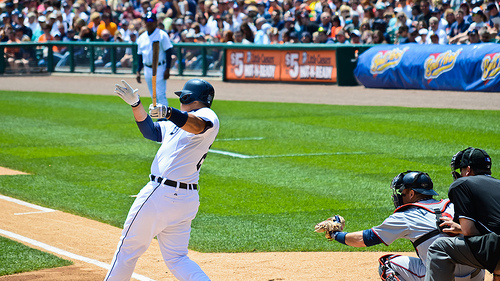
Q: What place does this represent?
A: It represents the field.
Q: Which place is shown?
A: It is a field.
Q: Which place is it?
A: It is a field.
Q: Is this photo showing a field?
A: Yes, it is showing a field.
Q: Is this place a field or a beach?
A: It is a field.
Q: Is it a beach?
A: No, it is a field.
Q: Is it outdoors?
A: Yes, it is outdoors.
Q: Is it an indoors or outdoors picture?
A: It is outdoors.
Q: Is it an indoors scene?
A: No, it is outdoors.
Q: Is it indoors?
A: No, it is outdoors.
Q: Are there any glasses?
A: No, there are no glasses.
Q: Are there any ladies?
A: No, there are no ladies.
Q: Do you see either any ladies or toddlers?
A: No, there are no ladies or toddlers.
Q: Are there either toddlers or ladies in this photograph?
A: No, there are no ladies or toddlers.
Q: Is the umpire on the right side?
A: Yes, the umpire is on the right of the image.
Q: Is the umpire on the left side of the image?
A: No, the umpire is on the right of the image.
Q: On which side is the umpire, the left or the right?
A: The umpire is on the right of the image.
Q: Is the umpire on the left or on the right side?
A: The umpire is on the right of the image.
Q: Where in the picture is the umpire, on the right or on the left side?
A: The umpire is on the right of the image.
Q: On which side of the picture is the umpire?
A: The umpire is on the right of the image.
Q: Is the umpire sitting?
A: Yes, the umpire is sitting.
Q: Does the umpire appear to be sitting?
A: Yes, the umpire is sitting.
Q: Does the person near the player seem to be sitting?
A: Yes, the umpire is sitting.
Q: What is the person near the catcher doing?
A: The umpire is sitting.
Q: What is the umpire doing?
A: The umpire is sitting.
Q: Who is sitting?
A: The umpire is sitting.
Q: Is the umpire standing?
A: No, the umpire is sitting.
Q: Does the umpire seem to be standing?
A: No, the umpire is sitting.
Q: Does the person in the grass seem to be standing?
A: No, the umpire is sitting.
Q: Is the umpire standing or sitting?
A: The umpire is sitting.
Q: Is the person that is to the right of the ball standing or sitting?
A: The umpire is sitting.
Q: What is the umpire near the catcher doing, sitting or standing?
A: The umpire is sitting.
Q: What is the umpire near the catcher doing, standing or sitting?
A: The umpire is sitting.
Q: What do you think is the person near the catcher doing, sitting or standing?
A: The umpire is sitting.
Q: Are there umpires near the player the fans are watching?
A: Yes, there is an umpire near the player.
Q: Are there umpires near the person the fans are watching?
A: Yes, there is an umpire near the player.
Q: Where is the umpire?
A: The umpire is on the field.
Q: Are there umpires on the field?
A: Yes, there is an umpire on the field.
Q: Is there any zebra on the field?
A: No, there is an umpire on the field.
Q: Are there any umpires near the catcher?
A: Yes, there is an umpire near the catcher.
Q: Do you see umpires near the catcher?
A: Yes, there is an umpire near the catcher.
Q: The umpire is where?
A: The umpire is in the grass.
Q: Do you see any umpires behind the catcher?
A: Yes, there is an umpire behind the catcher.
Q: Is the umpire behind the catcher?
A: Yes, the umpire is behind the catcher.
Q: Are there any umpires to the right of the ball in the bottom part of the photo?
A: Yes, there is an umpire to the right of the ball.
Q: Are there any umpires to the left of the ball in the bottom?
A: No, the umpire is to the right of the ball.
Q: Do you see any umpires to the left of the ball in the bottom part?
A: No, the umpire is to the right of the ball.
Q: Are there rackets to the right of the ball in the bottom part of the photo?
A: No, there is an umpire to the right of the ball.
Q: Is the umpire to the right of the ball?
A: Yes, the umpire is to the right of the ball.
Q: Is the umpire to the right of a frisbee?
A: No, the umpire is to the right of the ball.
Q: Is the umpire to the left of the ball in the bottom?
A: No, the umpire is to the right of the ball.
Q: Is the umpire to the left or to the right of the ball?
A: The umpire is to the right of the ball.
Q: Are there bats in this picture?
A: Yes, there is a bat.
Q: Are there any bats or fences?
A: Yes, there is a bat.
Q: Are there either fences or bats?
A: Yes, there is a bat.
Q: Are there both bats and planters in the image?
A: No, there is a bat but no planters.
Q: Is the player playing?
A: Yes, the player is playing.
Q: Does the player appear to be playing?
A: Yes, the player is playing.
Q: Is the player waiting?
A: No, the player is playing.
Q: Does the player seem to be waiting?
A: No, the player is playing.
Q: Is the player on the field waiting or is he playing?
A: The player is playing.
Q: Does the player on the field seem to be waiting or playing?
A: The player is playing.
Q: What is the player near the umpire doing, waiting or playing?
A: The player is playing.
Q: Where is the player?
A: The player is on the field.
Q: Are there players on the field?
A: Yes, there is a player on the field.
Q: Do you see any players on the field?
A: Yes, there is a player on the field.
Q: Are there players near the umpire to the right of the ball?
A: Yes, there is a player near the umpire.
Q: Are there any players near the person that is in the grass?
A: Yes, there is a player near the umpire.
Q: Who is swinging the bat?
A: The player is swinging the bat.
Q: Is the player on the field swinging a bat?
A: Yes, the player is swinging a bat.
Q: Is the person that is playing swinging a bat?
A: Yes, the player is swinging a bat.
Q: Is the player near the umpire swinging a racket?
A: No, the player is swinging a bat.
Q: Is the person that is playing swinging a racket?
A: No, the player is swinging a bat.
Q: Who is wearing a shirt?
A: The player is wearing a shirt.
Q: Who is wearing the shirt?
A: The player is wearing a shirt.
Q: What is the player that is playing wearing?
A: The player is wearing a shirt.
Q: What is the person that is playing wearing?
A: The player is wearing a shirt.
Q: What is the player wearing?
A: The player is wearing a shirt.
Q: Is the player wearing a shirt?
A: Yes, the player is wearing a shirt.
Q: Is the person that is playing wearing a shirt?
A: Yes, the player is wearing a shirt.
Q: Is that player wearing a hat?
A: No, the player is wearing a shirt.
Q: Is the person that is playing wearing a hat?
A: No, the player is wearing a shirt.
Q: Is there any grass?
A: Yes, there is grass.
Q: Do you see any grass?
A: Yes, there is grass.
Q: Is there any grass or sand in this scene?
A: Yes, there is grass.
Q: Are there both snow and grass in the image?
A: No, there is grass but no snow.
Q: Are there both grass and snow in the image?
A: No, there is grass but no snow.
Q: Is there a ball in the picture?
A: Yes, there is a ball.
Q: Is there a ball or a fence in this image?
A: Yes, there is a ball.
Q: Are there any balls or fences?
A: Yes, there is a ball.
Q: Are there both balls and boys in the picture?
A: No, there is a ball but no boys.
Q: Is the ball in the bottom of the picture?
A: Yes, the ball is in the bottom of the image.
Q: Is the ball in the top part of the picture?
A: No, the ball is in the bottom of the image.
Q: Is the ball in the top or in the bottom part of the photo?
A: The ball is in the bottom of the image.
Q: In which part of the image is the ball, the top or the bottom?
A: The ball is in the bottom of the image.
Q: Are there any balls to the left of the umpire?
A: Yes, there is a ball to the left of the umpire.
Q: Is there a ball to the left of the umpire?
A: Yes, there is a ball to the left of the umpire.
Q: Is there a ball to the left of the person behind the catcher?
A: Yes, there is a ball to the left of the umpire.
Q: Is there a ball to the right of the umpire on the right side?
A: No, the ball is to the left of the umpire.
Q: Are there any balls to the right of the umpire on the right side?
A: No, the ball is to the left of the umpire.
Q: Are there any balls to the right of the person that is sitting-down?
A: No, the ball is to the left of the umpire.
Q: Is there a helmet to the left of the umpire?
A: No, there is a ball to the left of the umpire.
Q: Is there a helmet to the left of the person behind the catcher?
A: No, there is a ball to the left of the umpire.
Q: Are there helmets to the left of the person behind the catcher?
A: No, there is a ball to the left of the umpire.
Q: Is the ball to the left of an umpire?
A: Yes, the ball is to the left of an umpire.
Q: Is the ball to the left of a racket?
A: No, the ball is to the left of an umpire.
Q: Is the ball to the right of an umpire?
A: No, the ball is to the left of an umpire.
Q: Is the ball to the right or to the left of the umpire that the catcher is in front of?
A: The ball is to the left of the umpire.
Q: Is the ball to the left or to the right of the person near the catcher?
A: The ball is to the left of the umpire.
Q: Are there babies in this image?
A: No, there are no babies.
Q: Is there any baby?
A: No, there are no babies.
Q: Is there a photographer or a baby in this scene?
A: No, there are no babies or photographers.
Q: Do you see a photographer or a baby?
A: No, there are no babies or photographers.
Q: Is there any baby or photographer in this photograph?
A: No, there are no babies or photographers.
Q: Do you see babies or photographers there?
A: No, there are no babies or photographers.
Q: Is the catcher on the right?
A: Yes, the catcher is on the right of the image.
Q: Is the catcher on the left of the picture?
A: No, the catcher is on the right of the image.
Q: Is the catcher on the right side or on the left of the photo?
A: The catcher is on the right of the image.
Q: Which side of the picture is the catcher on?
A: The catcher is on the right of the image.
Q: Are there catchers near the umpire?
A: Yes, there is a catcher near the umpire.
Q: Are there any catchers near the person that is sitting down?
A: Yes, there is a catcher near the umpire.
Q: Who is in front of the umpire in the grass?
A: The catcher is in front of the umpire.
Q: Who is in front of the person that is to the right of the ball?
A: The catcher is in front of the umpire.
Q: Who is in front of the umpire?
A: The catcher is in front of the umpire.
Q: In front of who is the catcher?
A: The catcher is in front of the umpire.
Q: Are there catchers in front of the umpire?
A: Yes, there is a catcher in front of the umpire.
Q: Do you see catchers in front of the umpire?
A: Yes, there is a catcher in front of the umpire.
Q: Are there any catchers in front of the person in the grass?
A: Yes, there is a catcher in front of the umpire.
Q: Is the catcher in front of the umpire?
A: Yes, the catcher is in front of the umpire.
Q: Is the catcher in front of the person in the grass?
A: Yes, the catcher is in front of the umpire.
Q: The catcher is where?
A: The catcher is on the field.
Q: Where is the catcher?
A: The catcher is on the field.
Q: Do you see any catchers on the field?
A: Yes, there is a catcher on the field.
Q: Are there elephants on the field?
A: No, there is a catcher on the field.